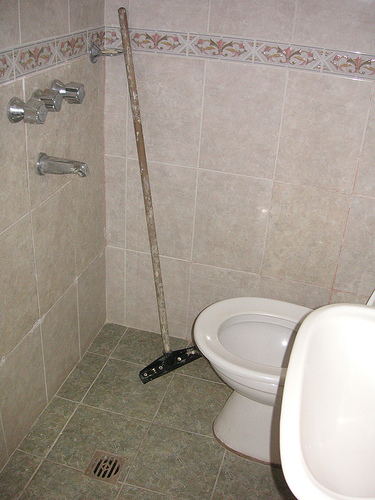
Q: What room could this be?
A: It is a bathroom.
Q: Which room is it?
A: It is a bathroom.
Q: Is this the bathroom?
A: Yes, it is the bathroom.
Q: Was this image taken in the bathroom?
A: Yes, it was taken in the bathroom.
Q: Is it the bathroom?
A: Yes, it is the bathroom.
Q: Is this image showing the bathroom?
A: Yes, it is showing the bathroom.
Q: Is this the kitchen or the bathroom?
A: It is the bathroom.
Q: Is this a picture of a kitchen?
A: No, the picture is showing a bathroom.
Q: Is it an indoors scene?
A: Yes, it is indoors.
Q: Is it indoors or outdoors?
A: It is indoors.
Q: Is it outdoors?
A: No, it is indoors.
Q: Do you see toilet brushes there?
A: No, there are no toilet brushes.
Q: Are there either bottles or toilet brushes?
A: No, there are no toilet brushes or bottles.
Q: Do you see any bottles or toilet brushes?
A: No, there are no toilet brushes or bottles.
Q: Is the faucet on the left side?
A: Yes, the faucet is on the left of the image.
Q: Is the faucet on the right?
A: No, the faucet is on the left of the image.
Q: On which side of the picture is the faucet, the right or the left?
A: The faucet is on the left of the image.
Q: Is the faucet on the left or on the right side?
A: The faucet is on the left of the image.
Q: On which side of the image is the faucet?
A: The faucet is on the left of the image.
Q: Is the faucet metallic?
A: Yes, the faucet is metallic.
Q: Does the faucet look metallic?
A: Yes, the faucet is metallic.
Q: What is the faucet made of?
A: The tap is made of metal.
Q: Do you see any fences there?
A: No, there are no fences.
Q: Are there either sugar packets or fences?
A: No, there are no fences or sugar packets.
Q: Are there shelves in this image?
A: No, there are no shelves.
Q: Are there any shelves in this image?
A: No, there are no shelves.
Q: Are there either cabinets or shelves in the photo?
A: No, there are no shelves or cabinets.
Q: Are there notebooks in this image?
A: No, there are no notebooks.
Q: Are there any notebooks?
A: No, there are no notebooks.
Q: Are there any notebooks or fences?
A: No, there are no notebooks or fences.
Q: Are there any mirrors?
A: No, there are no mirrors.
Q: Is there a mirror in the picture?
A: No, there are no mirrors.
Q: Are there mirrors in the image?
A: No, there are no mirrors.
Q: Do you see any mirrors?
A: No, there are no mirrors.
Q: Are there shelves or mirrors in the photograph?
A: No, there are no mirrors or shelves.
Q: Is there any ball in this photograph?
A: No, there are no balls.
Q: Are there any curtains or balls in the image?
A: No, there are no balls or curtains.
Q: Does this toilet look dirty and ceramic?
A: No, the toilet is ceramic but clean.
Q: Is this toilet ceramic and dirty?
A: No, the toilet is ceramic but clean.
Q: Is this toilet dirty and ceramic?
A: No, the toilet is ceramic but clean.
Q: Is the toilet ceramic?
A: Yes, the toilet is ceramic.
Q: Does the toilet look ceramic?
A: Yes, the toilet is ceramic.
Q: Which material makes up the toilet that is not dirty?
A: The toilet is made of porcelain.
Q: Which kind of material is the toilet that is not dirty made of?
A: The toilet is made of porcelain.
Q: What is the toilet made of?
A: The toilet is made of porcelain.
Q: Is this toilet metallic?
A: No, the toilet is ceramic.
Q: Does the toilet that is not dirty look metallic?
A: No, the toilet is ceramic.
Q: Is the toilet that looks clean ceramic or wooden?
A: The toilet is ceramic.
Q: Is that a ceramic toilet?
A: Yes, that is a ceramic toilet.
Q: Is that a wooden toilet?
A: No, that is a ceramic toilet.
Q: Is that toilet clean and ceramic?
A: Yes, the toilet is clean and ceramic.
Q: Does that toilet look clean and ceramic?
A: Yes, the toilet is clean and ceramic.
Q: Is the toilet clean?
A: Yes, the toilet is clean.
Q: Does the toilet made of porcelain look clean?
A: Yes, the toilet is clean.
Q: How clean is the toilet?
A: The toilet is clean.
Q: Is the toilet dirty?
A: No, the toilet is clean.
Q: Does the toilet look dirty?
A: No, the toilet is clean.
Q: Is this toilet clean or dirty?
A: The toilet is clean.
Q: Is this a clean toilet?
A: Yes, this is a clean toilet.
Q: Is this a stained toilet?
A: No, this is a clean toilet.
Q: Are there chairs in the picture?
A: No, there are no chairs.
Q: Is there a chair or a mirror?
A: No, there are no chairs or mirrors.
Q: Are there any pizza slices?
A: No, there are no pizza slices.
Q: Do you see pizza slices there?
A: No, there are no pizza slices.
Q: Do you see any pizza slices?
A: No, there are no pizza slices.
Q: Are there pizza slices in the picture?
A: No, there are no pizza slices.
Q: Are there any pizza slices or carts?
A: No, there are no pizza slices or carts.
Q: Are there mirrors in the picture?
A: No, there are no mirrors.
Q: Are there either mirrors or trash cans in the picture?
A: No, there are no mirrors or trash cans.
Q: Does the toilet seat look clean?
A: Yes, the toilet seat is clean.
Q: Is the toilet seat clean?
A: Yes, the toilet seat is clean.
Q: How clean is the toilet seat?
A: The toilet seat is clean.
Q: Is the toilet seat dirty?
A: No, the toilet seat is clean.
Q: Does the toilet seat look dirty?
A: No, the toilet seat is clean.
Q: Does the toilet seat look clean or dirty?
A: The toilet seat is clean.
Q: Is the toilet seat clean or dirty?
A: The toilet seat is clean.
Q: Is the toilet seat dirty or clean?
A: The toilet seat is clean.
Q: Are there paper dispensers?
A: No, there are no paper dispensers.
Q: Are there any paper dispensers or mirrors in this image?
A: No, there are no paper dispensers or mirrors.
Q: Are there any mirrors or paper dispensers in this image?
A: No, there are no paper dispensers or mirrors.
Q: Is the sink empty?
A: Yes, the sink is empty.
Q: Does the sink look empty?
A: Yes, the sink is empty.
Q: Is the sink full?
A: No, the sink is empty.